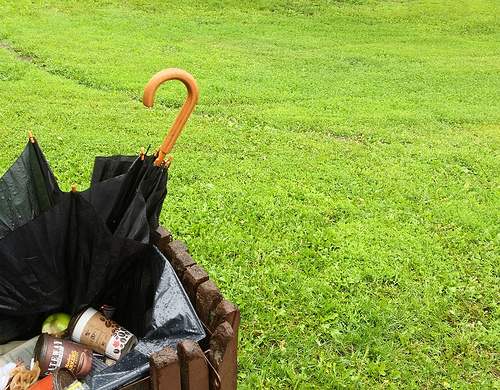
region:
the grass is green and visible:
[224, 33, 496, 347]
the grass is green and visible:
[234, 142, 444, 385]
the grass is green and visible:
[51, 67, 361, 379]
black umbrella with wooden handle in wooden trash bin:
[1, 27, 198, 357]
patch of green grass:
[298, 228, 401, 335]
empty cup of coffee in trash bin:
[65, 300, 140, 362]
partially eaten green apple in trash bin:
[34, 310, 72, 336]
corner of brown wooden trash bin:
[148, 224, 253, 389]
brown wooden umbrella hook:
[126, 53, 201, 166]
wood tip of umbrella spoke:
[21, 128, 41, 145]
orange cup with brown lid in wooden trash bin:
[13, 364, 77, 389]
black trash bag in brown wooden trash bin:
[137, 270, 195, 349]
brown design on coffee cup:
[96, 314, 118, 339]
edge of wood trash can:
[172, 212, 257, 384]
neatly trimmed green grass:
[334, 112, 441, 224]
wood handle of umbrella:
[133, 59, 207, 168]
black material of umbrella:
[9, 141, 172, 324]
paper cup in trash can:
[65, 297, 140, 364]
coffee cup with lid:
[28, 333, 98, 373]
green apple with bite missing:
[33, 307, 75, 346]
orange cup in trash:
[33, 362, 77, 388]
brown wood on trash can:
[178, 333, 213, 386]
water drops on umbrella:
[2, 159, 32, 214]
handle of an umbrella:
[133, 60, 200, 165]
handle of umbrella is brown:
[130, 64, 208, 165]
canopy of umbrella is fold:
[0, 139, 167, 310]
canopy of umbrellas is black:
[0, 124, 173, 344]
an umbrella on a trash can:
[1, 52, 254, 389]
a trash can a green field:
[6, 4, 499, 387]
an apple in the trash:
[24, 303, 78, 342]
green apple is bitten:
[36, 307, 72, 341]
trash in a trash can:
[5, 291, 136, 388]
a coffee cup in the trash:
[68, 301, 142, 366]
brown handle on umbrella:
[148, 58, 196, 181]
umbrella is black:
[37, 131, 170, 327]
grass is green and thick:
[143, 4, 403, 370]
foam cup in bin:
[69, 275, 151, 363]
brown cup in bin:
[0, 328, 116, 378]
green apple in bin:
[20, 314, 99, 353]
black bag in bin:
[64, 253, 219, 328]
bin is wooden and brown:
[93, 214, 280, 377]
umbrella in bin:
[28, 96, 259, 328]